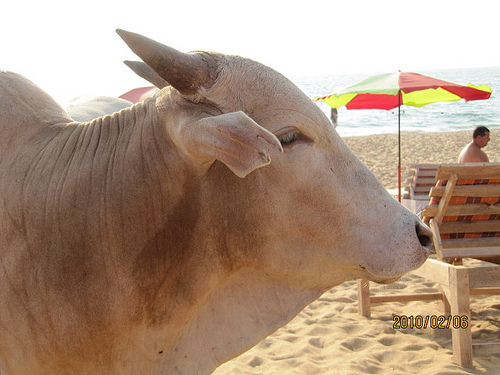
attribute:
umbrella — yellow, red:
[311, 66, 493, 208]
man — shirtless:
[457, 123, 494, 168]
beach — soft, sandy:
[211, 127, 499, 374]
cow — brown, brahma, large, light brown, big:
[3, 27, 435, 374]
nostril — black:
[411, 218, 434, 251]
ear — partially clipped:
[180, 110, 285, 180]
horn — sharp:
[115, 28, 216, 101]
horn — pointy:
[123, 58, 170, 93]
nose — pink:
[408, 216, 437, 263]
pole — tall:
[396, 88, 405, 213]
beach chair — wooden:
[403, 160, 451, 203]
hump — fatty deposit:
[1, 71, 75, 148]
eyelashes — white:
[278, 130, 299, 143]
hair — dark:
[472, 125, 488, 139]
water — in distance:
[3, 66, 496, 141]